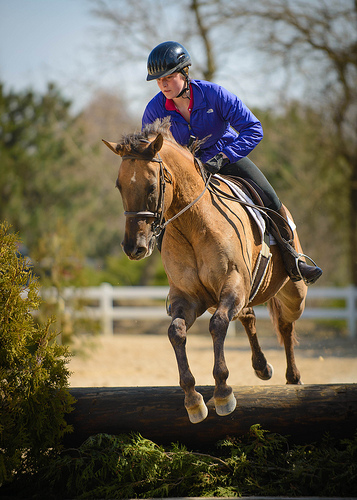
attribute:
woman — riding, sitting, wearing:
[104, 51, 259, 155]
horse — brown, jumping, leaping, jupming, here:
[127, 148, 258, 312]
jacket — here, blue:
[185, 90, 279, 142]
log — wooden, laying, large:
[101, 373, 355, 428]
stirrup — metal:
[256, 245, 329, 286]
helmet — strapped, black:
[140, 31, 241, 104]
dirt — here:
[98, 321, 191, 378]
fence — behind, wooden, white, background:
[104, 274, 158, 326]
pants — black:
[218, 151, 290, 284]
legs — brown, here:
[163, 303, 355, 376]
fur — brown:
[192, 214, 262, 268]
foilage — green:
[88, 421, 232, 497]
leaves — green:
[21, 134, 65, 213]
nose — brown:
[112, 229, 156, 270]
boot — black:
[267, 221, 353, 294]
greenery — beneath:
[64, 416, 351, 496]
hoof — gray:
[214, 380, 282, 435]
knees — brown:
[144, 315, 259, 355]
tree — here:
[264, 395, 348, 442]